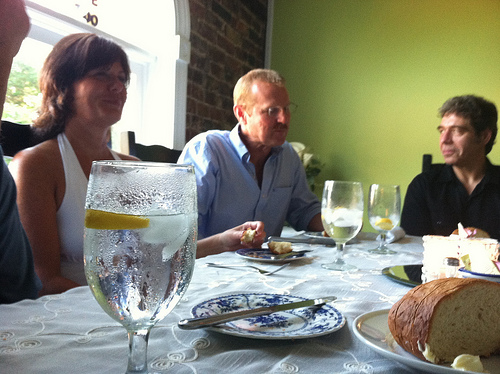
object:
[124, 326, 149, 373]
halter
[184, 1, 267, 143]
wall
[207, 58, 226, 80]
brick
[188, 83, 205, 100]
brick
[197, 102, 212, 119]
brick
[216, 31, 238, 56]
brick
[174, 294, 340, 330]
butter knife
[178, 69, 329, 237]
man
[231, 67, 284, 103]
hair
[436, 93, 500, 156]
hair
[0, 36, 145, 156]
window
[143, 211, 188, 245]
ice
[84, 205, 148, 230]
lemon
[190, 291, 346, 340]
plate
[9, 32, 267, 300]
woman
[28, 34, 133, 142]
hair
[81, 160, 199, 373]
glass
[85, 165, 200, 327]
condensation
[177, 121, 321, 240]
shirt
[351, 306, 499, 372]
plate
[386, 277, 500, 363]
bread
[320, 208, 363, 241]
drink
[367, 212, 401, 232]
drink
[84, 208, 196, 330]
drink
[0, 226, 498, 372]
table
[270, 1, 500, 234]
wall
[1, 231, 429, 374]
tablecloth